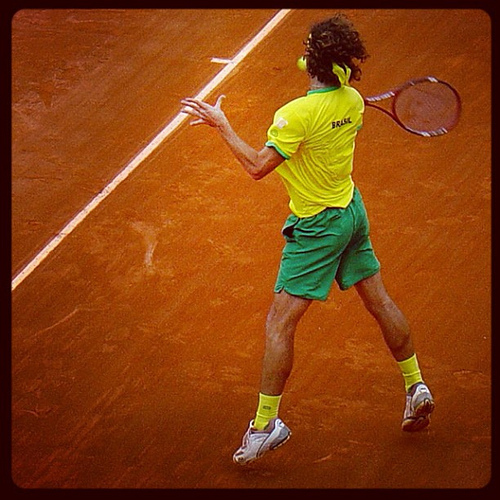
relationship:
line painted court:
[148, 123, 163, 159] [22, 283, 221, 491]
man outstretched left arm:
[182, 17, 440, 466] [179, 93, 303, 180]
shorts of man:
[270, 187, 382, 303] [182, 17, 440, 466]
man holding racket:
[182, 17, 440, 466] [362, 75, 463, 139]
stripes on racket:
[416, 127, 448, 137] [362, 75, 463, 139]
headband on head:
[330, 57, 360, 87] [301, 13, 368, 90]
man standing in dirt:
[176, 12, 441, 473] [27, 150, 230, 480]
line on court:
[16, 168, 140, 288] [0, 0, 495, 499]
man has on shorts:
[182, 17, 440, 466] [265, 191, 395, 301]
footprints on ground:
[55, 155, 465, 411] [57, 107, 230, 408]